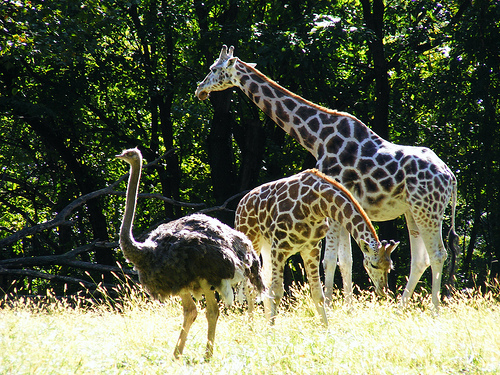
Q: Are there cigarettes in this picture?
A: No, there are no cigarettes.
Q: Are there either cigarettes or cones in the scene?
A: No, there are no cigarettes or cones.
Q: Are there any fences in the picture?
A: No, there are no fences.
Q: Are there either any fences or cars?
A: No, there are no fences or cars.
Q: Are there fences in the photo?
A: No, there are no fences.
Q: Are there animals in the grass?
A: Yes, there is an animal in the grass.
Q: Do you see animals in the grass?
A: Yes, there is an animal in the grass.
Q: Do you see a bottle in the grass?
A: No, there is an animal in the grass.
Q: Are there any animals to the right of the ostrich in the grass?
A: Yes, there is an animal to the right of the ostrich.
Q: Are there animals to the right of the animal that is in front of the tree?
A: Yes, there is an animal to the right of the ostrich.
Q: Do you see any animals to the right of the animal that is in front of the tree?
A: Yes, there is an animal to the right of the ostrich.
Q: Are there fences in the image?
A: No, there are no fences.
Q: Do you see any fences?
A: No, there are no fences.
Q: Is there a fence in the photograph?
A: No, there are no fences.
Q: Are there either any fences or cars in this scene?
A: No, there are no fences or cars.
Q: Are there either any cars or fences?
A: No, there are no fences or cars.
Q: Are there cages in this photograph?
A: No, there are no cages.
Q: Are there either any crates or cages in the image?
A: No, there are no cages or crates.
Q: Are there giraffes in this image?
A: Yes, there is a giraffe.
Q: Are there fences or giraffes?
A: Yes, there is a giraffe.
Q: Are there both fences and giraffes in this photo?
A: No, there is a giraffe but no fences.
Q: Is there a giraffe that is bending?
A: Yes, there is a giraffe that is bending.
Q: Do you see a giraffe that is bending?
A: Yes, there is a giraffe that is bending.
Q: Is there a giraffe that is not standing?
A: Yes, there is a giraffe that is bending.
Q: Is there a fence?
A: No, there are no fences.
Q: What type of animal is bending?
A: The animal is a giraffe.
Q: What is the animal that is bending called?
A: The animal is a giraffe.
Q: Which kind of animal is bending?
A: The animal is a giraffe.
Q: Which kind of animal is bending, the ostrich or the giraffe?
A: The giraffe is bending.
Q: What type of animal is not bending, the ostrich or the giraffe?
A: The ostrich is not bending.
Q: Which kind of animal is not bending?
A: The animal is an ostrich.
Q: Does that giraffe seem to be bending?
A: Yes, the giraffe is bending.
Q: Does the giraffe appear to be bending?
A: Yes, the giraffe is bending.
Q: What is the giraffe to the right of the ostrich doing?
A: The giraffe is bending.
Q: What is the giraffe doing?
A: The giraffe is bending.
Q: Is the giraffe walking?
A: No, the giraffe is bending.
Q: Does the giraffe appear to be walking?
A: No, the giraffe is bending.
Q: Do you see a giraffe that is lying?
A: No, there is a giraffe but it is bending.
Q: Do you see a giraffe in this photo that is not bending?
A: No, there is a giraffe but it is bending.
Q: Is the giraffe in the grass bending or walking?
A: The giraffe is bending.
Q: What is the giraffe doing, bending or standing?
A: The giraffe is bending.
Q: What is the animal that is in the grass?
A: The animal is a giraffe.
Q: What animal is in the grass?
A: The animal is a giraffe.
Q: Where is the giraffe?
A: The giraffe is in the grass.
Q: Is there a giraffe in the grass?
A: Yes, there is a giraffe in the grass.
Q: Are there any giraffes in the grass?
A: Yes, there is a giraffe in the grass.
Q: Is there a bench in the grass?
A: No, there is a giraffe in the grass.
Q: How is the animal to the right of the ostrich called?
A: The animal is a giraffe.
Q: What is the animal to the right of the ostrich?
A: The animal is a giraffe.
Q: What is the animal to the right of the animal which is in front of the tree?
A: The animal is a giraffe.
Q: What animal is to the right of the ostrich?
A: The animal is a giraffe.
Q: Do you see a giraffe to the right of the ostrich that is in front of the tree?
A: Yes, there is a giraffe to the right of the ostrich.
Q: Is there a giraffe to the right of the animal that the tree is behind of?
A: Yes, there is a giraffe to the right of the ostrich.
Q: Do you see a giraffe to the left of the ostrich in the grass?
A: No, the giraffe is to the right of the ostrich.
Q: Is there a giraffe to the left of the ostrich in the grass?
A: No, the giraffe is to the right of the ostrich.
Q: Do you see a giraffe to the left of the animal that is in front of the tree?
A: No, the giraffe is to the right of the ostrich.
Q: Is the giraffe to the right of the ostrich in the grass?
A: Yes, the giraffe is to the right of the ostrich.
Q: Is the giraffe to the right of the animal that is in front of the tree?
A: Yes, the giraffe is to the right of the ostrich.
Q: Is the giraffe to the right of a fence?
A: No, the giraffe is to the right of the ostrich.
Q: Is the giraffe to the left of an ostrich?
A: No, the giraffe is to the right of an ostrich.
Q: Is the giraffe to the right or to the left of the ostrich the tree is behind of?
A: The giraffe is to the right of the ostrich.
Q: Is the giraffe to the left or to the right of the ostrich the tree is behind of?
A: The giraffe is to the right of the ostrich.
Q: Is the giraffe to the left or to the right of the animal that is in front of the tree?
A: The giraffe is to the right of the ostrich.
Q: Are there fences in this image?
A: No, there are no fences.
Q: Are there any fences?
A: No, there are no fences.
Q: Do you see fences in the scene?
A: No, there are no fences.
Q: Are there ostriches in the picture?
A: Yes, there is an ostrich.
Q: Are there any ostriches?
A: Yes, there is an ostrich.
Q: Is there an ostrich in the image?
A: Yes, there is an ostrich.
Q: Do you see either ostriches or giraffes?
A: Yes, there is an ostrich.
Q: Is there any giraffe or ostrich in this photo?
A: Yes, there is an ostrich.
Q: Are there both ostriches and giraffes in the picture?
A: Yes, there are both an ostrich and a giraffe.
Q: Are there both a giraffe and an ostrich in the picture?
A: Yes, there are both an ostrich and a giraffe.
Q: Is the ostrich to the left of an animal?
A: Yes, the ostrich is to the left of an animal.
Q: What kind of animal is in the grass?
A: The animal is an ostrich.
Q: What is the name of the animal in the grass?
A: The animal is an ostrich.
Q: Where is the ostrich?
A: The ostrich is in the grass.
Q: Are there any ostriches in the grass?
A: Yes, there is an ostrich in the grass.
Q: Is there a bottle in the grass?
A: No, there is an ostrich in the grass.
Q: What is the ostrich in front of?
A: The ostrich is in front of the tree.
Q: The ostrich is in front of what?
A: The ostrich is in front of the tree.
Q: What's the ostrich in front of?
A: The ostrich is in front of the tree.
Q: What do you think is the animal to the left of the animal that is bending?
A: The animal is an ostrich.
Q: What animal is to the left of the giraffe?
A: The animal is an ostrich.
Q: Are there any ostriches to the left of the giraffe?
A: Yes, there is an ostrich to the left of the giraffe.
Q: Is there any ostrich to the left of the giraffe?
A: Yes, there is an ostrich to the left of the giraffe.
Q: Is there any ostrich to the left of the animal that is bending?
A: Yes, there is an ostrich to the left of the giraffe.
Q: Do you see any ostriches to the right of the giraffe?
A: No, the ostrich is to the left of the giraffe.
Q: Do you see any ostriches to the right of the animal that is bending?
A: No, the ostrich is to the left of the giraffe.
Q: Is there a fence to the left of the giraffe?
A: No, there is an ostrich to the left of the giraffe.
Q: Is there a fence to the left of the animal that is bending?
A: No, there is an ostrich to the left of the giraffe.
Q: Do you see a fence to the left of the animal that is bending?
A: No, there is an ostrich to the left of the giraffe.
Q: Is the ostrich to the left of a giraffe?
A: Yes, the ostrich is to the left of a giraffe.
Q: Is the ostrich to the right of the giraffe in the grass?
A: No, the ostrich is to the left of the giraffe.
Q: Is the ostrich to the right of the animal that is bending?
A: No, the ostrich is to the left of the giraffe.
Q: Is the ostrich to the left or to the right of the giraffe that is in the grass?
A: The ostrich is to the left of the giraffe.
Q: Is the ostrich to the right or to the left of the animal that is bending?
A: The ostrich is to the left of the giraffe.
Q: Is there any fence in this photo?
A: No, there are no fences.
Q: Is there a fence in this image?
A: No, there are no fences.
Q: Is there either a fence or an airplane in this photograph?
A: No, there are no fences or airplanes.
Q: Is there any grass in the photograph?
A: Yes, there is grass.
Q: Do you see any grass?
A: Yes, there is grass.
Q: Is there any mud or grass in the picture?
A: Yes, there is grass.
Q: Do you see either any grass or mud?
A: Yes, there is grass.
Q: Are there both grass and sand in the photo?
A: No, there is grass but no sand.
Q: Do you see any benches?
A: No, there are no benches.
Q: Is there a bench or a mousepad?
A: No, there are no benches or mouse pads.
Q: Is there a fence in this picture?
A: No, there are no fences.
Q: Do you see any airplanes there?
A: No, there are no airplanes.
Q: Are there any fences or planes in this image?
A: No, there are no planes or fences.